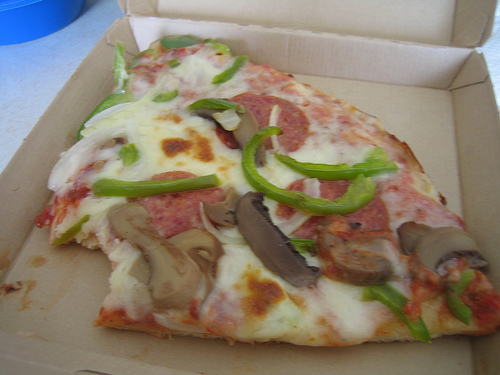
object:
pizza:
[26, 30, 499, 353]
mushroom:
[195, 97, 270, 170]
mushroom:
[197, 185, 245, 227]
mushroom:
[105, 198, 231, 317]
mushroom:
[232, 188, 323, 290]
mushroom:
[393, 216, 494, 284]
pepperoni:
[273, 172, 393, 250]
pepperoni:
[213, 88, 314, 157]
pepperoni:
[124, 167, 228, 244]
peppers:
[356, 275, 438, 349]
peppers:
[88, 172, 223, 199]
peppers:
[238, 122, 380, 219]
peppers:
[270, 143, 403, 183]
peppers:
[210, 51, 252, 87]